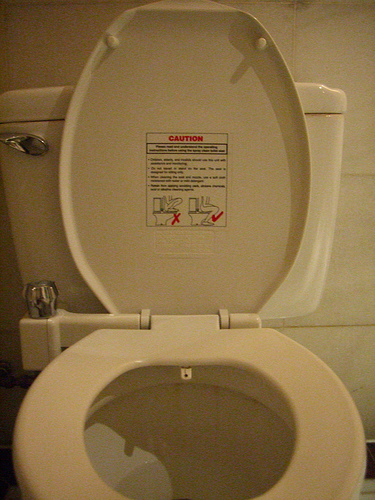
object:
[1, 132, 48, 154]
flush knob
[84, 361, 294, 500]
toilet bowl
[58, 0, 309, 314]
lid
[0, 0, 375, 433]
wall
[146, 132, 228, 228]
sign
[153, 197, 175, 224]
toilet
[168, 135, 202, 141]
writing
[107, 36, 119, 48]
peg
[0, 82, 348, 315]
top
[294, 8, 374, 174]
tile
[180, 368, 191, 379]
metal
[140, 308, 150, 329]
hinge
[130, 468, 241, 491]
water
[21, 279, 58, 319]
knob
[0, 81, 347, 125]
lid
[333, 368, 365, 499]
trim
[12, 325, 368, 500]
seat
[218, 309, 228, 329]
hinge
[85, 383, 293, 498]
shadow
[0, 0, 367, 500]
toilet